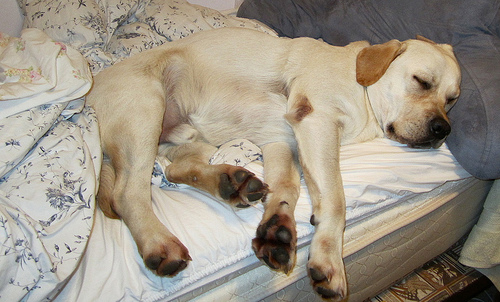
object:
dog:
[82, 36, 464, 301]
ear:
[354, 43, 404, 86]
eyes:
[445, 95, 457, 106]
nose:
[430, 119, 451, 136]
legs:
[296, 125, 350, 264]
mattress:
[57, 135, 480, 301]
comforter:
[0, 0, 278, 301]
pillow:
[237, 3, 499, 180]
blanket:
[1, 25, 94, 120]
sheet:
[56, 137, 476, 301]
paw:
[250, 221, 298, 276]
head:
[353, 36, 463, 149]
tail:
[92, 162, 118, 220]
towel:
[457, 179, 498, 292]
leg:
[160, 121, 218, 184]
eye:
[415, 76, 432, 90]